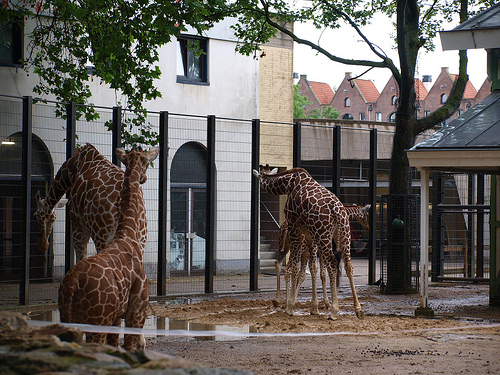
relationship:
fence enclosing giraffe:
[5, 89, 490, 294] [57, 146, 161, 355]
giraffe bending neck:
[29, 130, 214, 363] [41, 166, 71, 211]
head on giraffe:
[117, 145, 161, 185] [59, 146, 171, 348]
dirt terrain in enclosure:
[0, 273, 497, 373] [2, 81, 497, 368]